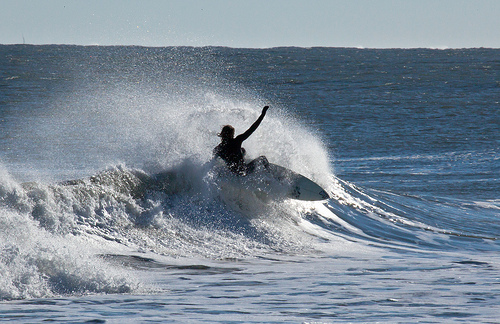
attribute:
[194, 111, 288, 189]
person — wet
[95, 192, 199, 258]
wave — rising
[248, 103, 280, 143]
arm — up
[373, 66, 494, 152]
ocean — present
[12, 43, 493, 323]
water — clear